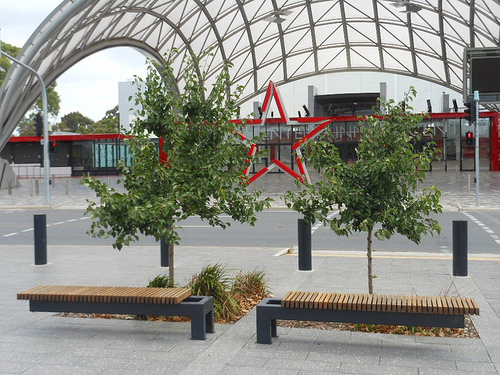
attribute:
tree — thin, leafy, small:
[282, 83, 445, 294]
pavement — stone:
[6, 257, 483, 361]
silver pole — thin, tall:
[467, 86, 484, 196]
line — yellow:
[287, 250, 495, 260]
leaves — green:
[97, 75, 453, 246]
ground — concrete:
[5, 167, 499, 373]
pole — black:
[449, 219, 471, 277]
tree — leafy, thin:
[92, 59, 268, 304]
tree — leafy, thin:
[275, 98, 463, 315]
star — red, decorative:
[215, 82, 338, 190]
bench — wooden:
[247, 262, 499, 348]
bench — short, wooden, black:
[12, 274, 214, 351]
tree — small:
[77, 44, 272, 285]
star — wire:
[215, 73, 367, 262]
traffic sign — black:
[458, 126, 477, 149]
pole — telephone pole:
[0, 49, 52, 206]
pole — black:
[296, 218, 313, 281]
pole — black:
[32, 215, 52, 266]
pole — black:
[157, 232, 169, 267]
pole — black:
[297, 217, 315, 270]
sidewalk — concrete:
[12, 261, 491, 367]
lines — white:
[59, 217, 74, 227]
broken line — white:
[468, 219, 499, 251]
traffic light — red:
[469, 130, 474, 139]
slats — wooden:
[280, 288, 480, 315]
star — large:
[202, 79, 334, 188]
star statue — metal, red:
[202, 80, 333, 188]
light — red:
[466, 131, 470, 138]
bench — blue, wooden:
[255, 290, 478, 343]